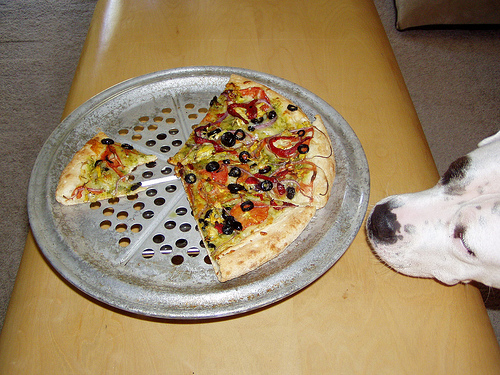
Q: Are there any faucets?
A: No, there are no faucets.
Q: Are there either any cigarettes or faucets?
A: No, there are no faucets or cigarettes.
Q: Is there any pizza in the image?
A: Yes, there is a pizza.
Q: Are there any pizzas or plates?
A: Yes, there is a pizza.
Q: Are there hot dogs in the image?
A: No, there are no hot dogs.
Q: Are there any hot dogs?
A: No, there are no hot dogs.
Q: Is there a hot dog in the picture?
A: No, there are no hot dogs.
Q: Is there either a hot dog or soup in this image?
A: No, there are no hot dogs or soup.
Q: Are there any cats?
A: No, there are no cats.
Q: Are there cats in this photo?
A: No, there are no cats.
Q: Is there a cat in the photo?
A: No, there are no cats.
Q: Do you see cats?
A: No, there are no cats.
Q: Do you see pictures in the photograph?
A: No, there are no pictures.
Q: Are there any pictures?
A: No, there are no pictures.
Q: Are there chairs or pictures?
A: No, there are no pictures or chairs.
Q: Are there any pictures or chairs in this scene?
A: No, there are no pictures or chairs.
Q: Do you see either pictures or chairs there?
A: No, there are no pictures or chairs.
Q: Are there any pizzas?
A: Yes, there is a pizza.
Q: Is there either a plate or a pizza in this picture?
A: Yes, there is a pizza.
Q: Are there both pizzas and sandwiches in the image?
A: No, there is a pizza but no sandwiches.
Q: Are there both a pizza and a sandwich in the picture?
A: No, there is a pizza but no sandwiches.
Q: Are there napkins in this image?
A: No, there are no napkins.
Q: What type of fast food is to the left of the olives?
A: The food is a pizza.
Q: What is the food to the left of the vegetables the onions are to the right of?
A: The food is a pizza.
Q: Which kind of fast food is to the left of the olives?
A: The food is a pizza.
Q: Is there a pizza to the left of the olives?
A: Yes, there is a pizza to the left of the olives.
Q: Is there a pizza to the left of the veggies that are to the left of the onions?
A: Yes, there is a pizza to the left of the olives.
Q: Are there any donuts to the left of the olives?
A: No, there is a pizza to the left of the olives.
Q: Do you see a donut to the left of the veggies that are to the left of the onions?
A: No, there is a pizza to the left of the olives.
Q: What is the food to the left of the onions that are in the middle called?
A: The food is a pizza.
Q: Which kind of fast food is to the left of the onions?
A: The food is a pizza.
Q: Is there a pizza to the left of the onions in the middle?
A: Yes, there is a pizza to the left of the onions.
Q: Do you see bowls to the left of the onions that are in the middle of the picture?
A: No, there is a pizza to the left of the onions.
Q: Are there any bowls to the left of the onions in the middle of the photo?
A: No, there is a pizza to the left of the onions.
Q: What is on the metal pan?
A: The pizza is on the pan.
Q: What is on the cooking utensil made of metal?
A: The pizza is on the pan.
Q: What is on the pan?
A: The pizza is on the pan.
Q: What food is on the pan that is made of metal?
A: The food is a pizza.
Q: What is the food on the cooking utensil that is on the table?
A: The food is a pizza.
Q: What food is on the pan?
A: The food is a pizza.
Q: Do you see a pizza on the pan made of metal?
A: Yes, there is a pizza on the pan.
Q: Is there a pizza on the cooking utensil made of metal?
A: Yes, there is a pizza on the pan.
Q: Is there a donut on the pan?
A: No, there is a pizza on the pan.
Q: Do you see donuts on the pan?
A: No, there is a pizza on the pan.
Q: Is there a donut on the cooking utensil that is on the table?
A: No, there is a pizza on the pan.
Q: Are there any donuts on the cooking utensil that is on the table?
A: No, there is a pizza on the pan.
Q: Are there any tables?
A: Yes, there is a table.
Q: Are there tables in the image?
A: Yes, there is a table.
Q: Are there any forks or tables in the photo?
A: Yes, there is a table.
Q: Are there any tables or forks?
A: Yes, there is a table.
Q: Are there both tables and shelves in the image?
A: No, there is a table but no shelves.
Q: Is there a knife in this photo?
A: No, there are no knives.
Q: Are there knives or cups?
A: No, there are no knives or cups.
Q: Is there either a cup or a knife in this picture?
A: No, there are no knives or cups.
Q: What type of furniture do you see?
A: The furniture is a table.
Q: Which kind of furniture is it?
A: The piece of furniture is a table.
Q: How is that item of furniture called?
A: This is a table.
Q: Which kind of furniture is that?
A: This is a table.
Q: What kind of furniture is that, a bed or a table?
A: This is a table.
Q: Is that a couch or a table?
A: That is a table.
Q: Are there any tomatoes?
A: Yes, there is a tomato.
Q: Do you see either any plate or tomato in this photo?
A: Yes, there is a tomato.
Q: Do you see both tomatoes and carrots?
A: No, there is a tomato but no carrots.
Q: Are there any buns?
A: No, there are no buns.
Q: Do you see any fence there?
A: No, there are no fences.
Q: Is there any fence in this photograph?
A: No, there are no fences.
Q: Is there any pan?
A: Yes, there is a pan.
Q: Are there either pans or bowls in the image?
A: Yes, there is a pan.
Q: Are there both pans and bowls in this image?
A: No, there is a pan but no bowls.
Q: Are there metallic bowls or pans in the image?
A: Yes, there is a metal pan.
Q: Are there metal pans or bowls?
A: Yes, there is a metal pan.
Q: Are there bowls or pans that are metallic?
A: Yes, the pan is metallic.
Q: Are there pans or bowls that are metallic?
A: Yes, the pan is metallic.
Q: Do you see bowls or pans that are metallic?
A: Yes, the pan is metallic.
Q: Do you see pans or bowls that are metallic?
A: Yes, the pan is metallic.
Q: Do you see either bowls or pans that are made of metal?
A: Yes, the pan is made of metal.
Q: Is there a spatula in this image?
A: No, there are no spatulas.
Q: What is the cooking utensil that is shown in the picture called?
A: The cooking utensil is a pan.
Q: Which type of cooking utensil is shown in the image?
A: The cooking utensil is a pan.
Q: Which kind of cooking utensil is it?
A: The cooking utensil is a pan.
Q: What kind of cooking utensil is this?
A: This is a pan.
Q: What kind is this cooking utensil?
A: This is a pan.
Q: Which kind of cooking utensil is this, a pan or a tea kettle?
A: This is a pan.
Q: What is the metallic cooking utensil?
A: The cooking utensil is a pan.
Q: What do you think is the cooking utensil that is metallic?
A: The cooking utensil is a pan.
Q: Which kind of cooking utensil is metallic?
A: The cooking utensil is a pan.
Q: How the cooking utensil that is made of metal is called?
A: The cooking utensil is a pan.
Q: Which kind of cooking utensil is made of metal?
A: The cooking utensil is a pan.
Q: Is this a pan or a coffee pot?
A: This is a pan.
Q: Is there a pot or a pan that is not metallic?
A: No, there is a pan but it is metallic.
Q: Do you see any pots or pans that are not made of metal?
A: No, there is a pan but it is made of metal.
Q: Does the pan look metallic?
A: Yes, the pan is metallic.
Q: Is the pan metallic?
A: Yes, the pan is metallic.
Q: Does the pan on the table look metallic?
A: Yes, the pan is metallic.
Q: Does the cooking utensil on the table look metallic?
A: Yes, the pan is metallic.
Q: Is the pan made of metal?
A: Yes, the pan is made of metal.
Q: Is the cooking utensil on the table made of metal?
A: Yes, the pan is made of metal.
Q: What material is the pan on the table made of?
A: The pan is made of metal.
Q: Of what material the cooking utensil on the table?
A: The pan is made of metal.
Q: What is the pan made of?
A: The pan is made of metal.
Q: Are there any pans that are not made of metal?
A: No, there is a pan but it is made of metal.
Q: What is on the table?
A: The pan is on the table.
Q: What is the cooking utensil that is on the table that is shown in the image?
A: The cooking utensil is a pan.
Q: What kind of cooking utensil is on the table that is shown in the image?
A: The cooking utensil is a pan.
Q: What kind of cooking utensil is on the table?
A: The cooking utensil is a pan.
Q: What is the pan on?
A: The pan is on the table.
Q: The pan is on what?
A: The pan is on the table.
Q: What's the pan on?
A: The pan is on the table.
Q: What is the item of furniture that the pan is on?
A: The piece of furniture is a table.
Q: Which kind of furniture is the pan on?
A: The pan is on the table.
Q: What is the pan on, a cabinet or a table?
A: The pan is on a table.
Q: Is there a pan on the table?
A: Yes, there is a pan on the table.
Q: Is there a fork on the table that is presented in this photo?
A: No, there is a pan on the table.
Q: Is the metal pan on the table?
A: Yes, the pan is on the table.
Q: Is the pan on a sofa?
A: No, the pan is on the table.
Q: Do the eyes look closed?
A: Yes, the eyes are closed.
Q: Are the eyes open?
A: No, the eyes are closed.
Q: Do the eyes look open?
A: No, the eyes are closed.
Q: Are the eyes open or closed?
A: The eyes are closed.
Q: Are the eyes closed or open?
A: The eyes are closed.